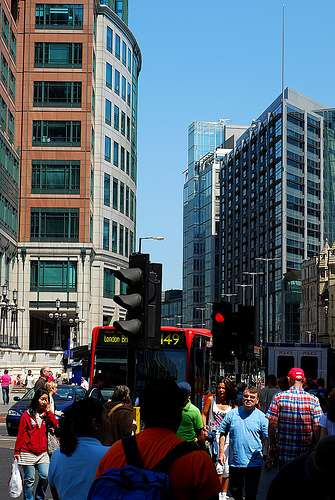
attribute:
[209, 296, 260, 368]
stoplight — black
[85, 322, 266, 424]
bus — red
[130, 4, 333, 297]
sky — blue, clear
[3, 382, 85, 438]
car — blue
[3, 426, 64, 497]
street — crowded, busy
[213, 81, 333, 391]
building — tall, large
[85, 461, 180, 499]
backpack — blue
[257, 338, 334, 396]
van — police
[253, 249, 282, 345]
street light — tall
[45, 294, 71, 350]
street light — old fashioned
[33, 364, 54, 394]
man — bald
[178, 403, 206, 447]
shirt — green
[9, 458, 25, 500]
bag — white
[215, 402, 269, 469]
shirt — blue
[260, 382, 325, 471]
shirt — red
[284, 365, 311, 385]
hat — red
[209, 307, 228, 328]
traffic light — red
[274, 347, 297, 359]
police — red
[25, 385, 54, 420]
hair — black